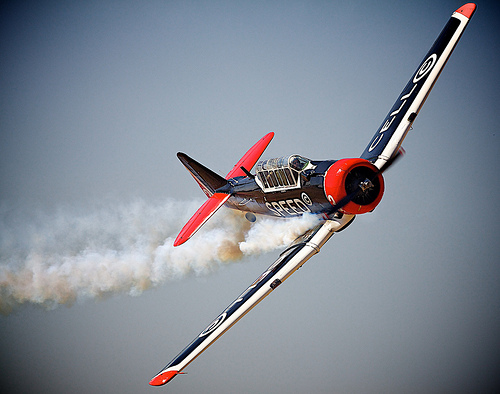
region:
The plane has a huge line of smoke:
[18, 212, 193, 302]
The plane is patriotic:
[145, 128, 465, 306]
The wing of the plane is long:
[149, 230, 351, 389]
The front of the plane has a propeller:
[313, 150, 411, 225]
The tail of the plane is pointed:
[152, 132, 265, 236]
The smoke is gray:
[8, 229, 158, 344]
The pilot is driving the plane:
[267, 151, 332, 188]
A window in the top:
[256, 159, 323, 187]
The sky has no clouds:
[32, 87, 144, 159]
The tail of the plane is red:
[171, 194, 214, 242]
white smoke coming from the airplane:
[12, 199, 192, 252]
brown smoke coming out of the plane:
[211, 223, 257, 268]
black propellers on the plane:
[320, 146, 419, 223]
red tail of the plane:
[143, 108, 280, 273]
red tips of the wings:
[145, 357, 184, 391]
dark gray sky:
[75, 44, 265, 106]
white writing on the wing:
[346, 3, 456, 180]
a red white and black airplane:
[130, 6, 484, 389]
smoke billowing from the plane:
[3, 189, 352, 327]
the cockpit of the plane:
[243, 138, 325, 205]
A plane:
[222, 156, 367, 261]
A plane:
[214, 121, 314, 289]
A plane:
[223, 219, 293, 293]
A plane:
[277, 211, 351, 360]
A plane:
[281, 179, 344, 284]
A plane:
[254, 211, 288, 300]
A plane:
[229, 145, 339, 379]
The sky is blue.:
[121, 26, 291, 90]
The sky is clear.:
[151, 20, 321, 95]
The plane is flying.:
[120, 3, 485, 382]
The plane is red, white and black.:
[102, 4, 485, 386]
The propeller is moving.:
[293, 138, 424, 235]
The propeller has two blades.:
[297, 137, 420, 235]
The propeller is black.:
[301, 140, 417, 230]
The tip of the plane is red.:
[313, 145, 399, 220]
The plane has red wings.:
[142, 117, 276, 255]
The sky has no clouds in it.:
[124, 24, 335, 111]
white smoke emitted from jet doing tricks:
[34, 199, 149, 304]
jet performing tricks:
[122, 12, 426, 342]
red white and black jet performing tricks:
[154, 27, 456, 348]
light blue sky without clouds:
[12, 23, 142, 128]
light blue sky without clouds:
[137, 26, 280, 103]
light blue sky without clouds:
[333, 236, 428, 348]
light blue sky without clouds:
[276, 18, 375, 83]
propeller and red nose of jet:
[310, 146, 424, 228]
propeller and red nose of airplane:
[293, 134, 434, 249]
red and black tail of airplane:
[153, 123, 273, 243]